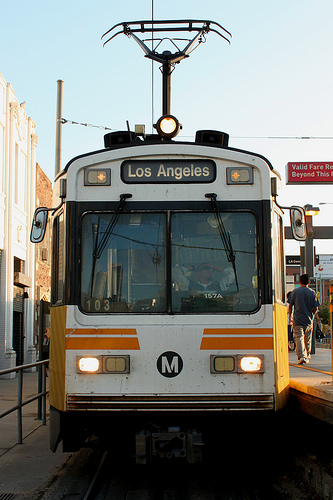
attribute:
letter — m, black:
[156, 352, 185, 379]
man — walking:
[285, 275, 320, 367]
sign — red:
[286, 160, 331, 185]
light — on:
[82, 170, 112, 184]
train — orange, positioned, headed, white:
[32, 131, 310, 467]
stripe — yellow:
[290, 358, 331, 375]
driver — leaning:
[170, 261, 236, 313]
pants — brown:
[290, 322, 317, 366]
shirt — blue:
[286, 288, 320, 327]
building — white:
[2, 73, 38, 378]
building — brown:
[36, 162, 51, 357]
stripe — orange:
[61, 325, 141, 352]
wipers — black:
[89, 193, 240, 291]